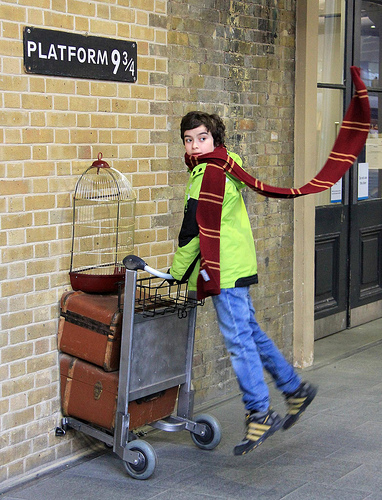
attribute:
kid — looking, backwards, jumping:
[165, 110, 317, 455]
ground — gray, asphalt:
[4, 318, 379, 498]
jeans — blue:
[208, 278, 314, 422]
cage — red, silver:
[67, 151, 142, 294]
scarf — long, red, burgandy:
[167, 67, 377, 309]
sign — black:
[21, 23, 143, 84]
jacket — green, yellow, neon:
[165, 149, 264, 294]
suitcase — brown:
[58, 290, 129, 372]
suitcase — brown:
[53, 351, 183, 437]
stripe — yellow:
[325, 148, 356, 160]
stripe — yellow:
[336, 115, 372, 127]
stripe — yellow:
[257, 174, 269, 192]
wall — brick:
[0, 1, 306, 491]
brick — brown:
[111, 94, 140, 115]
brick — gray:
[148, 69, 175, 87]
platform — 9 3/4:
[6, 5, 378, 499]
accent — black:
[176, 198, 208, 245]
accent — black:
[175, 252, 207, 285]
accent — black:
[233, 272, 262, 289]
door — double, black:
[312, 0, 350, 351]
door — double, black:
[346, 4, 380, 329]